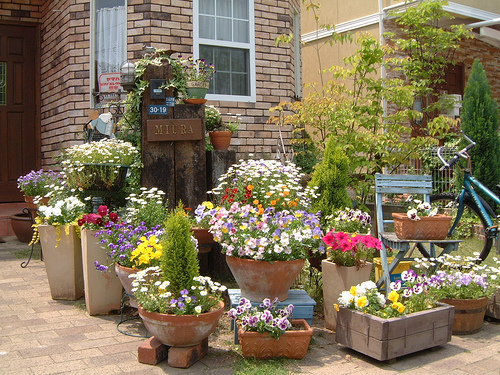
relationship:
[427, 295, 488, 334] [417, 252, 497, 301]
barrel with flowers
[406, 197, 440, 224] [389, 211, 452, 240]
flowers in planter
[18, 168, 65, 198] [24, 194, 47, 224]
flowers in planter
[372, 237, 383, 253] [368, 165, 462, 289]
flower next to chair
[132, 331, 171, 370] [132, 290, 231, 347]
brick underneath pot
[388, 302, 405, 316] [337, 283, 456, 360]
flower on planter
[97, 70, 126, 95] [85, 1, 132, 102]
sign in window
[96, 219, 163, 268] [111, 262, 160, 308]
flowers in planter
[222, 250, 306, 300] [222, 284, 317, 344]
pot sitting on top of stool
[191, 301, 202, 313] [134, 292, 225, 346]
flower blooming inside pot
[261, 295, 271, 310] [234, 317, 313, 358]
flower blooming inside pot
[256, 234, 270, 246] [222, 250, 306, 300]
flower blooming inside pot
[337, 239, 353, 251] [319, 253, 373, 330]
flower blooming inside pot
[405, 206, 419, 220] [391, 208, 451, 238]
flower blooming inside pot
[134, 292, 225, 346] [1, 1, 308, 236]
pot standing front of house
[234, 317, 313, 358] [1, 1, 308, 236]
pot standing front of house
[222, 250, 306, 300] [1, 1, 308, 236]
pot standing front of house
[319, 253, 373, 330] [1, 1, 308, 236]
pot standing front of house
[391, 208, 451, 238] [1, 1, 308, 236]
pot standing front of house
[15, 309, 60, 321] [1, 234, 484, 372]
brick covering sidewalk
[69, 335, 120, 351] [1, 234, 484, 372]
brick covering sidewalk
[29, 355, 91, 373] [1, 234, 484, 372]
brick covering sidewalk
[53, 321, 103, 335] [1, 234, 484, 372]
brick covering sidewalk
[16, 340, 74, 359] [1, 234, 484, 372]
brick covering sidewalk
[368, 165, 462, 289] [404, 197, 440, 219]
chair holding pansies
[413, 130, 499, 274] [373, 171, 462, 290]
bicycle behind chair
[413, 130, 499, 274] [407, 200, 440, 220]
bicycle behind flowers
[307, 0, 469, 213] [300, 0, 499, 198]
bush beside home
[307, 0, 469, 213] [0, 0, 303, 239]
bush beside home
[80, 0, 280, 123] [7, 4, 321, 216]
windows on angles of house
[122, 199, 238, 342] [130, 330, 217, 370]
planter with bricks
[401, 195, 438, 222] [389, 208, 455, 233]
pansies in pot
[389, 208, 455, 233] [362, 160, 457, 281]
pot on chair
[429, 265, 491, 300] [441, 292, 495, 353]
pansies blooming in barrel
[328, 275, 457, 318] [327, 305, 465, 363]
flowers blooming in container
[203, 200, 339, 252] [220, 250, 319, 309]
pansies in pot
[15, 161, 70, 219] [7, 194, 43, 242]
flowers in stand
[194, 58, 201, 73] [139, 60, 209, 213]
flower planted on display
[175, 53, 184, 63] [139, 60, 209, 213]
flower planted on display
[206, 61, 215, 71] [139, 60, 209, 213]
flower planted on display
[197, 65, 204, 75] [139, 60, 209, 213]
flower planted on display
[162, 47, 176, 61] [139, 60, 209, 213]
flower planted on display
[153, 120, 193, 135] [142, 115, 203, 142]
miura painted on sign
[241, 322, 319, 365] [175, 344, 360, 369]
pot on ground